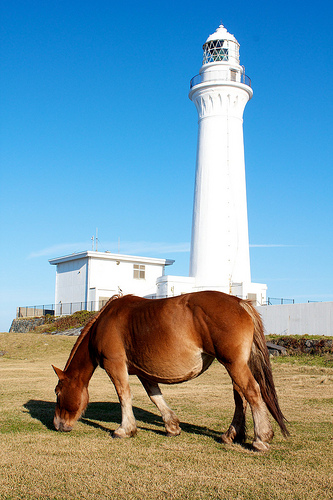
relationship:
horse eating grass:
[49, 288, 292, 452] [6, 417, 145, 453]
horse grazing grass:
[49, 288, 299, 455] [147, 472, 269, 498]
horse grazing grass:
[49, 288, 292, 452] [64, 446, 271, 494]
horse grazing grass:
[49, 288, 299, 455] [63, 451, 264, 498]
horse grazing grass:
[49, 288, 299, 455] [63, 449, 315, 498]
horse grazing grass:
[49, 288, 299, 455] [44, 444, 322, 496]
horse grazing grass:
[49, 288, 299, 455] [46, 432, 318, 497]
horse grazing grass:
[49, 288, 299, 455] [58, 435, 303, 497]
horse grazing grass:
[49, 288, 299, 455] [15, 434, 320, 494]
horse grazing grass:
[49, 288, 292, 452] [2, 339, 318, 492]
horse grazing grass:
[49, 288, 299, 455] [113, 458, 297, 497]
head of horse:
[47, 361, 90, 433] [49, 288, 299, 455]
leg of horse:
[98, 353, 136, 438] [49, 288, 299, 455]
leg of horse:
[139, 373, 183, 437] [49, 288, 299, 455]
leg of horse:
[225, 358, 277, 454] [49, 288, 299, 455]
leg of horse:
[222, 384, 248, 449] [49, 288, 299, 455]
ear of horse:
[49, 362, 66, 381] [49, 288, 299, 455]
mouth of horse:
[54, 418, 66, 434] [49, 288, 299, 455]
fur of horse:
[57, 292, 251, 416] [49, 288, 292, 452]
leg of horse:
[227, 384, 248, 428] [49, 288, 299, 455]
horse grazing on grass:
[49, 288, 299, 455] [2, 333, 330, 498]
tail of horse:
[249, 299, 293, 441] [49, 288, 299, 455]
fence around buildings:
[14, 292, 331, 320] [46, 20, 270, 316]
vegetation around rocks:
[273, 352, 330, 366] [290, 339, 328, 358]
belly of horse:
[128, 336, 212, 385] [49, 288, 299, 455]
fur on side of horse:
[110, 298, 198, 364] [49, 288, 299, 455]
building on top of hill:
[44, 249, 176, 318] [11, 309, 95, 333]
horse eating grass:
[49, 288, 299, 455] [5, 398, 330, 495]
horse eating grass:
[49, 288, 299, 455] [3, 379, 329, 498]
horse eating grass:
[49, 288, 299, 455] [4, 377, 332, 489]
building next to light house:
[44, 249, 176, 318] [185, 21, 261, 285]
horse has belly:
[49, 288, 299, 455] [128, 336, 215, 385]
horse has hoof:
[49, 288, 299, 455] [162, 414, 185, 435]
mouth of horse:
[57, 420, 67, 434] [49, 288, 299, 455]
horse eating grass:
[49, 288, 299, 455] [1, 422, 106, 498]